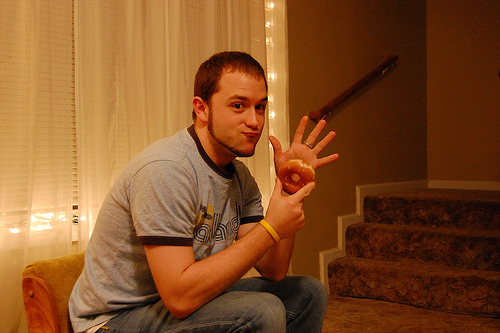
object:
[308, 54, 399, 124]
rail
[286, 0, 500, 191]
wall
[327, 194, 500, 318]
stairs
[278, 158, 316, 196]
doughnut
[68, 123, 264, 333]
shirt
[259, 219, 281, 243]
bracelet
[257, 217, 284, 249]
wrist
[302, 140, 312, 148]
ring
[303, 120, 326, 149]
finger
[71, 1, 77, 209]
blinds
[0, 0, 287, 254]
window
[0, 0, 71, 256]
curtain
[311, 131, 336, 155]
finger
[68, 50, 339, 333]
man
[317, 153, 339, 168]
finger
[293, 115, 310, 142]
finger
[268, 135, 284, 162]
finger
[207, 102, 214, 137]
beard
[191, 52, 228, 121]
hair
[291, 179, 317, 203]
index finger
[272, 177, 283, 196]
thumb finger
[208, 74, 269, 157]
face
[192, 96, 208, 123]
ear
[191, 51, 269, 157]
head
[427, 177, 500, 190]
molding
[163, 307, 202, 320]
right elbow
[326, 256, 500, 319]
stair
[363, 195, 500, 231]
stair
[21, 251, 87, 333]
chair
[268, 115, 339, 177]
hand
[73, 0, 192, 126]
curtain